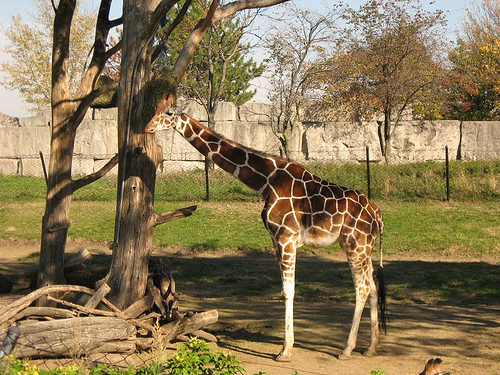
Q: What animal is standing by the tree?
A: Giraffe.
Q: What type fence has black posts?
A: Chain link.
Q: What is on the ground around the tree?
A: Wood logs.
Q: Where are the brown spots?
A: On the giraffe.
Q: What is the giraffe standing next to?
A: A tree with no leaves.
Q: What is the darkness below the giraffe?
A: Shadow of tree on ground.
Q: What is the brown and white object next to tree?
A: Giraffe standing in the forest.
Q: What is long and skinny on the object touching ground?
A: Leg of the giraffe.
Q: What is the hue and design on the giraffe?
A: Brown and cream color with polygons shape.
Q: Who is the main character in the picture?
A: Baby giraffe standing up.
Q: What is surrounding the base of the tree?
A: Pile of broken tree branches.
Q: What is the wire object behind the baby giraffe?
A: Chain link fence holding the giraffe in.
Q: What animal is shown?
A: Giraffe.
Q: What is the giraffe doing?
A: Eating.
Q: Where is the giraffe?
A: In a zoo.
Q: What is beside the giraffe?
A: A tree.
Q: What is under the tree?
A: Logs.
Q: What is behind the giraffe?
A: A fence.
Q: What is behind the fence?
A: Trees.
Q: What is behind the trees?
A: A wall.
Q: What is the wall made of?
A: Stone.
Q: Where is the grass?
A: ON the ground.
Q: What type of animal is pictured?
A: A giraffe.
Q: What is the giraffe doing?
A: Standing.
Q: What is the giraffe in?
A: A zoo enclosure.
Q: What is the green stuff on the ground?
A: Grass.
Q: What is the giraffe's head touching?
A: A tree.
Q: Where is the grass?
A: On the ground.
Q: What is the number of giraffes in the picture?
A: One.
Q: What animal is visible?
A: Giraffe.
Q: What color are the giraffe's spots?
A: Brown.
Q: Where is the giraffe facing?
A: Left.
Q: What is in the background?
A: Wall.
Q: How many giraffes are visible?
A: 1.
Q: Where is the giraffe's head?
A: Near the tree.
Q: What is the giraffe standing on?
A: Dirt.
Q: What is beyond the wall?
A: Trees.